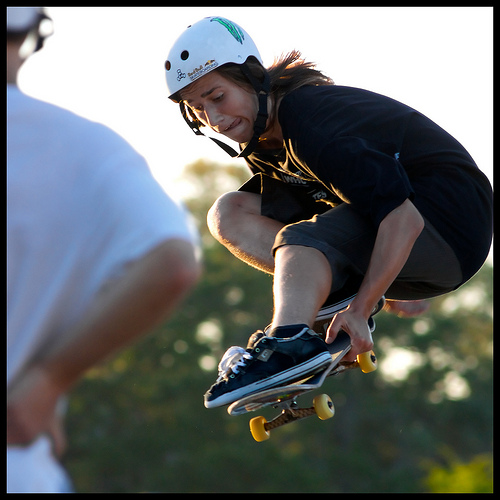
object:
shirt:
[8, 82, 195, 499]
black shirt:
[235, 77, 493, 291]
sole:
[197, 362, 336, 410]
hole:
[165, 60, 171, 71]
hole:
[180, 50, 189, 61]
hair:
[226, 51, 332, 89]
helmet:
[163, 15, 265, 99]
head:
[164, 18, 272, 144]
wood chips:
[368, 46, 460, 107]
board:
[205, 320, 378, 413]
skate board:
[226, 312, 386, 444]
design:
[209, 16, 249, 44]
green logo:
[203, 15, 250, 46]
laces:
[216, 345, 254, 377]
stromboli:
[245, 413, 271, 446]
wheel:
[357, 349, 377, 373]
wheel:
[249, 414, 269, 439]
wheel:
[312, 391, 334, 418]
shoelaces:
[212, 342, 253, 371]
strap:
[181, 65, 272, 156]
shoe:
[203, 325, 333, 409]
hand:
[324, 302, 375, 362]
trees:
[62, 174, 492, 496]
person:
[0, 5, 207, 495]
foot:
[313, 289, 391, 321]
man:
[162, 10, 494, 408]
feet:
[203, 323, 331, 411]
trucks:
[249, 350, 374, 447]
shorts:
[238, 173, 458, 306]